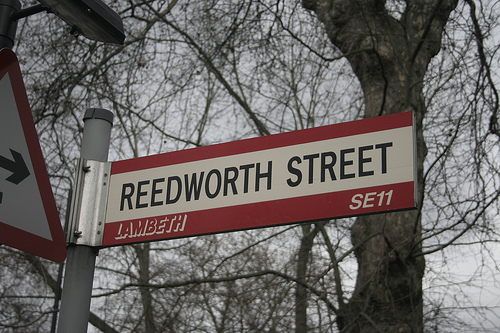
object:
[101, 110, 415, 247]
sign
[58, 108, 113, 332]
pole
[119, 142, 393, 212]
writing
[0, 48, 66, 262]
sign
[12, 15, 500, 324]
trees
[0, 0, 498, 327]
sky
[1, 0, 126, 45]
light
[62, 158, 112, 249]
brace